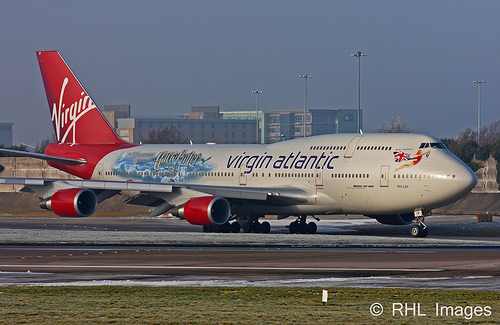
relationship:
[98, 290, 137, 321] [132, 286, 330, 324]
part of grass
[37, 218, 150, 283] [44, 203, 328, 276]
part of runway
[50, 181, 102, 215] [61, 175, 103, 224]
part of engine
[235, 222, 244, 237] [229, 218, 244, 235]
part of wheel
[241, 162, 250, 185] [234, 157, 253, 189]
part of door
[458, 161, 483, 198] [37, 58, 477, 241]
tip of plane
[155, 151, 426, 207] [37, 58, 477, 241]
side of plane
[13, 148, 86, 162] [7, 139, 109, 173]
edge of wing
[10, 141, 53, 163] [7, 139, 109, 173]
part of wing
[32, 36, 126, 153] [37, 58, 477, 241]
tail of plane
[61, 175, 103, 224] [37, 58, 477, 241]
engine on plane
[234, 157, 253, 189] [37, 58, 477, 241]
door on plane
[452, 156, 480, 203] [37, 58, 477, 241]
nose on plane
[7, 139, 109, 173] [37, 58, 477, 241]
wing on plane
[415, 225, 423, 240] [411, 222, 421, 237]
front of wheel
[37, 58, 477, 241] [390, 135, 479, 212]
plane has cockpit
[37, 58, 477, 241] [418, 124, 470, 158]
plane has windshield